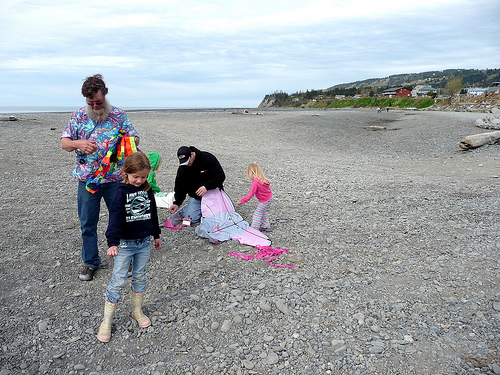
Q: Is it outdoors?
A: Yes, it is outdoors.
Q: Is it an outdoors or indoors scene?
A: It is outdoors.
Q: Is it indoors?
A: No, it is outdoors.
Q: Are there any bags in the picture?
A: No, there are no bags.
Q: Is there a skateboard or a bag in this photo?
A: No, there are no bags or skateboards.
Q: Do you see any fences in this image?
A: No, there are no fences.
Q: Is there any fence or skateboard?
A: No, there are no fences or skateboards.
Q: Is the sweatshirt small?
A: Yes, the sweatshirt is small.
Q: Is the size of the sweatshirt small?
A: Yes, the sweatshirt is small.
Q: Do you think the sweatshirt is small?
A: Yes, the sweatshirt is small.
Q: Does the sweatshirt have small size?
A: Yes, the sweatshirt is small.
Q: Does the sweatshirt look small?
A: Yes, the sweatshirt is small.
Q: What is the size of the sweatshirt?
A: The sweatshirt is small.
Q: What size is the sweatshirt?
A: The sweatshirt is small.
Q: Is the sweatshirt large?
A: No, the sweatshirt is small.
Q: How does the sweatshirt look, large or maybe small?
A: The sweatshirt is small.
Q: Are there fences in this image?
A: No, there are no fences.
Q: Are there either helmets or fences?
A: No, there are no fences or helmets.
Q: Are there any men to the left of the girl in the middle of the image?
A: Yes, there is a man to the left of the girl.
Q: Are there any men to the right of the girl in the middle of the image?
A: No, the man is to the left of the girl.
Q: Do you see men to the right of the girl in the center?
A: No, the man is to the left of the girl.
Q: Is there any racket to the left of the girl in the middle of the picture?
A: No, there is a man to the left of the girl.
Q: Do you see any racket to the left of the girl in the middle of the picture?
A: No, there is a man to the left of the girl.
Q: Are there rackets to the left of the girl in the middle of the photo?
A: No, there is a man to the left of the girl.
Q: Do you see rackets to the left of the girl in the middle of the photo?
A: No, there is a man to the left of the girl.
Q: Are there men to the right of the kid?
A: Yes, there is a man to the right of the kid.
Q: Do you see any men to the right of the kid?
A: Yes, there is a man to the right of the kid.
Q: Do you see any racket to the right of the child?
A: No, there is a man to the right of the child.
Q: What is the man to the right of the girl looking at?
A: The man is looking at the ground.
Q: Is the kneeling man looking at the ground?
A: Yes, the man is looking at the ground.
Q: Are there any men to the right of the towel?
A: Yes, there is a man to the right of the towel.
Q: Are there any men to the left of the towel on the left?
A: No, the man is to the right of the towel.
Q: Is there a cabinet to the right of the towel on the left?
A: No, there is a man to the right of the towel.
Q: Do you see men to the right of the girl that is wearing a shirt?
A: Yes, there is a man to the right of the girl.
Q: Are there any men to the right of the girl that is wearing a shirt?
A: Yes, there is a man to the right of the girl.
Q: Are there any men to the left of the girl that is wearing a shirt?
A: No, the man is to the right of the girl.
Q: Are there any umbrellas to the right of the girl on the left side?
A: No, there is a man to the right of the girl.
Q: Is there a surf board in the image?
A: No, there are no surfboards.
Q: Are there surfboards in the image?
A: No, there are no surfboards.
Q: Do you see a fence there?
A: No, there are no fences.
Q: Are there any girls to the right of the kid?
A: Yes, there is a girl to the right of the kid.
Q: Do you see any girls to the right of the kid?
A: Yes, there is a girl to the right of the kid.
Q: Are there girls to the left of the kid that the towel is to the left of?
A: No, the girl is to the right of the kid.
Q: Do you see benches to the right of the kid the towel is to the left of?
A: No, there is a girl to the right of the child.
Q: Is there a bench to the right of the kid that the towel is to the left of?
A: No, there is a girl to the right of the child.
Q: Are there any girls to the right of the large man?
A: Yes, there is a girl to the right of the man.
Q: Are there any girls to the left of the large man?
A: No, the girl is to the right of the man.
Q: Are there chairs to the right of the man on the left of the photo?
A: No, there is a girl to the right of the man.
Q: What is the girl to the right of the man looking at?
A: The girl is looking at the ground.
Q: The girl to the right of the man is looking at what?
A: The girl is looking at the ground.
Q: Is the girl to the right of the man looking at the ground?
A: Yes, the girl is looking at the ground.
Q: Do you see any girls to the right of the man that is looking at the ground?
A: Yes, there is a girl to the right of the man.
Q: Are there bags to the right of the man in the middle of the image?
A: No, there is a girl to the right of the man.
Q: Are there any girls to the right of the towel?
A: Yes, there is a girl to the right of the towel.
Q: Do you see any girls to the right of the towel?
A: Yes, there is a girl to the right of the towel.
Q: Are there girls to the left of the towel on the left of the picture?
A: No, the girl is to the right of the towel.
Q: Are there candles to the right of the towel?
A: No, there is a girl to the right of the towel.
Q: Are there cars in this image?
A: No, there are no cars.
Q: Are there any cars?
A: No, there are no cars.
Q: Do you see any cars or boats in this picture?
A: No, there are no cars or boats.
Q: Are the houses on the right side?
A: Yes, the houses are on the right of the image.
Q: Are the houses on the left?
A: No, the houses are on the right of the image.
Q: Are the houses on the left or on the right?
A: The houses are on the right of the image.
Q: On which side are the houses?
A: The houses are on the right of the image.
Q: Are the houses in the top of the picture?
A: Yes, the houses are in the top of the image.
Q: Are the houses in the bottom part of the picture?
A: No, the houses are in the top of the image.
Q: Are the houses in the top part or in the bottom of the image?
A: The houses are in the top of the image.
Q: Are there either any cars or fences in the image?
A: No, there are no cars or fences.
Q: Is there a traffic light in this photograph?
A: No, there are no traffic lights.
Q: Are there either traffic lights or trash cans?
A: No, there are no traffic lights or trash cans.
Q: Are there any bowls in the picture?
A: No, there are no bowls.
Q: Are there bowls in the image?
A: No, there are no bowls.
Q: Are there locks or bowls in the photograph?
A: No, there are no bowls or locks.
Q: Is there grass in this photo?
A: Yes, there is grass.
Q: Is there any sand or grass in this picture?
A: Yes, there is grass.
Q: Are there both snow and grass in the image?
A: No, there is grass but no snow.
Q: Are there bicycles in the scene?
A: No, there are no bicycles.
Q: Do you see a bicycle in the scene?
A: No, there are no bicycles.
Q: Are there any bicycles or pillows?
A: No, there are no bicycles or pillows.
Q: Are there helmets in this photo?
A: No, there are no helmets.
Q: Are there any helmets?
A: No, there are no helmets.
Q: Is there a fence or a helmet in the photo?
A: No, there are no helmets or fences.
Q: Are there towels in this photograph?
A: Yes, there is a towel.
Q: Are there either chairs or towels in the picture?
A: Yes, there is a towel.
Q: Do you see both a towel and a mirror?
A: No, there is a towel but no mirrors.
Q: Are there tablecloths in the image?
A: No, there are no tablecloths.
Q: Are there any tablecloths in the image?
A: No, there are no tablecloths.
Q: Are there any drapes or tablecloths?
A: No, there are no tablecloths or drapes.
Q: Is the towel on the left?
A: Yes, the towel is on the left of the image.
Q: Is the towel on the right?
A: No, the towel is on the left of the image.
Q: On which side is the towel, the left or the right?
A: The towel is on the left of the image.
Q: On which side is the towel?
A: The towel is on the left of the image.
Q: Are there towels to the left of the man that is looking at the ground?
A: Yes, there is a towel to the left of the man.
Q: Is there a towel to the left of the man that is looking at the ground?
A: Yes, there is a towel to the left of the man.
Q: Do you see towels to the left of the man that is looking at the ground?
A: Yes, there is a towel to the left of the man.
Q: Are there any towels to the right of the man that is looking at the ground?
A: No, the towel is to the left of the man.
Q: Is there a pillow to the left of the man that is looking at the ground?
A: No, there is a towel to the left of the man.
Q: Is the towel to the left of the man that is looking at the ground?
A: Yes, the towel is to the left of the man.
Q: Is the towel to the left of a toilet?
A: No, the towel is to the left of the man.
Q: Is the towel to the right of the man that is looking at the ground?
A: No, the towel is to the left of the man.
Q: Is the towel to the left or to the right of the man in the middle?
A: The towel is to the left of the man.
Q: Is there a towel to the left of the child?
A: Yes, there is a towel to the left of the child.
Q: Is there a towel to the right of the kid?
A: No, the towel is to the left of the kid.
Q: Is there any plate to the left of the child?
A: No, there is a towel to the left of the child.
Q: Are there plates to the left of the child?
A: No, there is a towel to the left of the child.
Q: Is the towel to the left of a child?
A: Yes, the towel is to the left of a child.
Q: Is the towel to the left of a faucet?
A: No, the towel is to the left of a child.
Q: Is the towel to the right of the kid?
A: No, the towel is to the left of the kid.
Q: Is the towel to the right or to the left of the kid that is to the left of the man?
A: The towel is to the left of the child.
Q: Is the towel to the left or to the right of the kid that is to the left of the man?
A: The towel is to the left of the child.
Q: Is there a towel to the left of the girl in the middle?
A: Yes, there is a towel to the left of the girl.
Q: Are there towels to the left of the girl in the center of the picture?
A: Yes, there is a towel to the left of the girl.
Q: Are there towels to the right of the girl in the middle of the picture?
A: No, the towel is to the left of the girl.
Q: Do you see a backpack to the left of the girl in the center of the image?
A: No, there is a towel to the left of the girl.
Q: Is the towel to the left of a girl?
A: Yes, the towel is to the left of a girl.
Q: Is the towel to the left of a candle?
A: No, the towel is to the left of a girl.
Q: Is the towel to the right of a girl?
A: No, the towel is to the left of a girl.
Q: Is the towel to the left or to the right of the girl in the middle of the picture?
A: The towel is to the left of the girl.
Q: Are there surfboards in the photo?
A: No, there are no surfboards.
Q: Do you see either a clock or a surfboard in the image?
A: No, there are no surfboards or clocks.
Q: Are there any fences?
A: No, there are no fences.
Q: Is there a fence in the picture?
A: No, there are no fences.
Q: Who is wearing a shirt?
A: The girl is wearing a shirt.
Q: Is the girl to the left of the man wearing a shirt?
A: Yes, the girl is wearing a shirt.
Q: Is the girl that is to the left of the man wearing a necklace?
A: No, the girl is wearing a shirt.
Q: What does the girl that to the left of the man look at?
A: The girl looks at the ground.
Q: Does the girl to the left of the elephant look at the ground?
A: Yes, the girl looks at the ground.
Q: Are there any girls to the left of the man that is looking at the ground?
A: Yes, there is a girl to the left of the man.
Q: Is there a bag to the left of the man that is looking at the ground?
A: No, there is a girl to the left of the man.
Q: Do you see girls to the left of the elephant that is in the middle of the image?
A: Yes, there is a girl to the left of the elephant.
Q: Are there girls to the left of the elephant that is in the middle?
A: Yes, there is a girl to the left of the elephant.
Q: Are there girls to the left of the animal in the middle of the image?
A: Yes, there is a girl to the left of the elephant.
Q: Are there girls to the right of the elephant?
A: No, the girl is to the left of the elephant.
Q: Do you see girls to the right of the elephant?
A: No, the girl is to the left of the elephant.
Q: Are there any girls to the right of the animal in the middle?
A: No, the girl is to the left of the elephant.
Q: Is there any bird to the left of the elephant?
A: No, there is a girl to the left of the elephant.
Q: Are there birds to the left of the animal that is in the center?
A: No, there is a girl to the left of the elephant.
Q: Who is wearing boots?
A: The girl is wearing boots.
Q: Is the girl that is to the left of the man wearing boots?
A: Yes, the girl is wearing boots.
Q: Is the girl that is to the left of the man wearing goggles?
A: No, the girl is wearing boots.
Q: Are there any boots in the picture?
A: Yes, there are boots.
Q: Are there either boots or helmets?
A: Yes, there are boots.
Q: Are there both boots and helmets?
A: No, there are boots but no helmets.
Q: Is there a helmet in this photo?
A: No, there are no helmets.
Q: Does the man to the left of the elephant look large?
A: Yes, the man is large.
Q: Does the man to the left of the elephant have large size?
A: Yes, the man is large.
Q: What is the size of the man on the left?
A: The man is large.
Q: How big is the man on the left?
A: The man is large.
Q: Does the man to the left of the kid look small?
A: No, the man is large.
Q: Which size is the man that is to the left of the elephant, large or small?
A: The man is large.